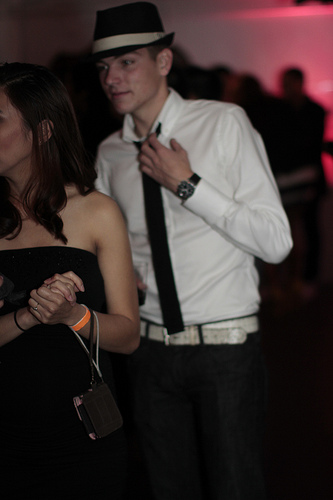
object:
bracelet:
[69, 301, 92, 332]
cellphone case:
[70, 375, 124, 444]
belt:
[136, 315, 261, 349]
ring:
[33, 302, 39, 312]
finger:
[61, 270, 85, 292]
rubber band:
[13, 310, 28, 333]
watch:
[174, 172, 202, 201]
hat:
[80, 2, 175, 64]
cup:
[132, 259, 148, 307]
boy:
[89, 0, 295, 497]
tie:
[130, 122, 185, 340]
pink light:
[159, 1, 333, 187]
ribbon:
[90, 29, 169, 51]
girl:
[0, 61, 141, 500]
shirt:
[91, 86, 295, 328]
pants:
[120, 318, 263, 499]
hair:
[0, 61, 98, 247]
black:
[0, 245, 112, 500]